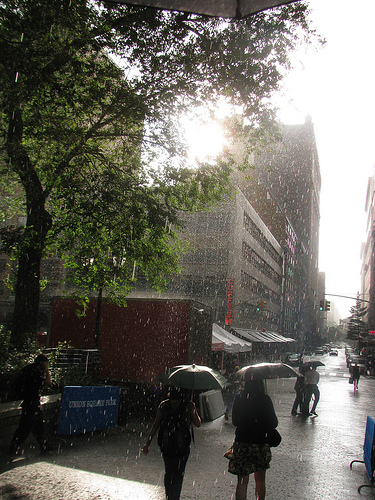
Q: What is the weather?
A: It's raining.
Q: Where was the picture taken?
A: On a city street.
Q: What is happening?
A: It's raining.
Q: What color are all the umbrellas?
A: Black.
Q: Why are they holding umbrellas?
A: It's raining.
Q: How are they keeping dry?
A: They are holding umbrellas.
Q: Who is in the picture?
A: People walking int he city.